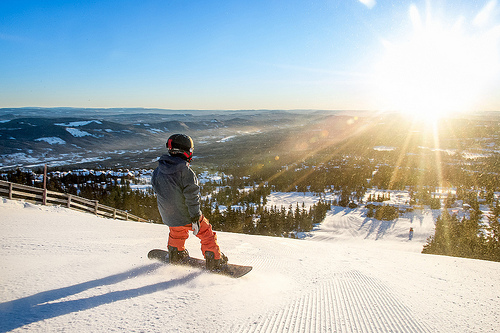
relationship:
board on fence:
[44, 187, 65, 200] [26, 181, 138, 222]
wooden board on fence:
[0, 187, 7, 196] [1, 172, 153, 222]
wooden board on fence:
[12, 181, 42, 192] [1, 172, 153, 222]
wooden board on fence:
[11, 190, 42, 200] [1, 172, 153, 222]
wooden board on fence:
[98, 200, 115, 213] [1, 172, 153, 222]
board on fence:
[47, 190, 68, 204] [1, 172, 153, 222]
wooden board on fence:
[12, 181, 42, 192] [1, 173, 149, 227]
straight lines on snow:
[223, 266, 445, 331] [2, 211, 497, 331]